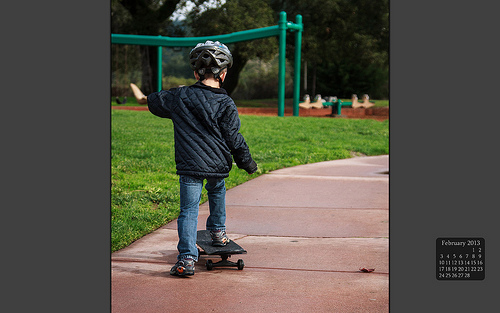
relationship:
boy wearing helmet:
[129, 40, 258, 276] [191, 37, 232, 73]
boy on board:
[129, 40, 258, 276] [196, 230, 247, 271]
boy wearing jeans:
[129, 40, 258, 276] [173, 172, 223, 268]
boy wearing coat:
[129, 40, 258, 276] [149, 84, 254, 178]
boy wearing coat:
[129, 40, 258, 276] [147, 82, 258, 177]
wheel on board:
[196, 254, 212, 266] [200, 230, 245, 270]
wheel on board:
[205, 261, 217, 271] [196, 226, 245, 267]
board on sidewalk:
[196, 230, 247, 271] [116, 155, 390, 311]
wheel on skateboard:
[205, 260, 213, 271] [191, 218, 248, 278]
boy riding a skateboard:
[129, 40, 258, 276] [170, 216, 250, 276]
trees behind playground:
[295, 27, 371, 90] [211, 8, 373, 147]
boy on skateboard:
[129, 40, 258, 276] [189, 219, 243, 278]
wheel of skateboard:
[205, 260, 213, 271] [183, 224, 245, 258]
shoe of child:
[167, 251, 202, 282] [153, 36, 258, 144]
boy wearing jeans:
[129, 40, 258, 276] [159, 161, 240, 275]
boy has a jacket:
[129, 40, 258, 276] [145, 81, 248, 180]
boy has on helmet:
[151, 27, 251, 138] [185, 25, 231, 81]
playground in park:
[227, 14, 352, 125] [133, 2, 373, 198]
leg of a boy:
[164, 174, 213, 255] [153, 28, 277, 190]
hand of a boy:
[123, 77, 166, 117] [170, 32, 242, 143]